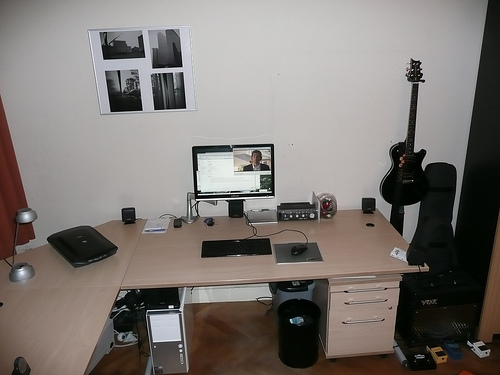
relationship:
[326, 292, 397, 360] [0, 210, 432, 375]
drawer of desk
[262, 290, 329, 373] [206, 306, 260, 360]
can on floor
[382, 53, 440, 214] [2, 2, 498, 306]
guitar on wall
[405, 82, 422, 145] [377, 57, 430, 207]
neck on guitar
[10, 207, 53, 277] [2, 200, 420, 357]
lamp on desk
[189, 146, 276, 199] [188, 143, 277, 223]
screen of computer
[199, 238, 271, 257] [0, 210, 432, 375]
keyboard on desk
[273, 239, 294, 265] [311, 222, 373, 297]
mouse pad on desk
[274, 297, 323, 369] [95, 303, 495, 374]
can on floor